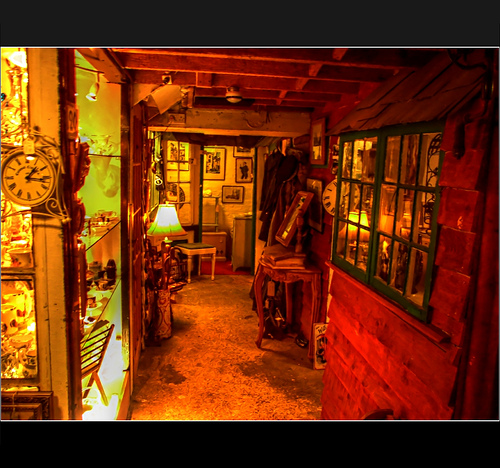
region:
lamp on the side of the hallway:
[146, 194, 189, 241]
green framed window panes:
[323, 123, 452, 332]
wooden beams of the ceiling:
[101, 48, 425, 125]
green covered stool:
[172, 230, 222, 287]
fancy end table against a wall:
[241, 245, 329, 366]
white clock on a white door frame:
[3, 148, 57, 218]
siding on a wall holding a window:
[314, 119, 484, 418]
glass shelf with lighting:
[51, 42, 129, 411]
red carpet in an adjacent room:
[193, 248, 256, 277]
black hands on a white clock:
[26, 165, 48, 192]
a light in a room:
[138, 148, 227, 263]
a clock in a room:
[9, 155, 59, 208]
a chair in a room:
[174, 204, 240, 282]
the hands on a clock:
[23, 163, 48, 187]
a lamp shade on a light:
[151, 193, 198, 239]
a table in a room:
[226, 232, 348, 357]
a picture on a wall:
[206, 157, 276, 195]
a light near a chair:
[161, 193, 244, 295]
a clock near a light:
[11, 133, 251, 231]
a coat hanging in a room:
[236, 160, 308, 257]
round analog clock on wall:
[0, 136, 62, 232]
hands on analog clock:
[16, 161, 56, 194]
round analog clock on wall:
[319, 172, 365, 232]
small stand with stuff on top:
[234, 178, 339, 366]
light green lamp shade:
[137, 189, 189, 256]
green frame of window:
[368, 111, 445, 326]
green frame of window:
[326, 123, 367, 297]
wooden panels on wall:
[313, 326, 393, 416]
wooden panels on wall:
[325, 293, 462, 431]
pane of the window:
[350, 139, 362, 177]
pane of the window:
[340, 146, 350, 177]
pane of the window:
[358, 231, 370, 270]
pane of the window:
[371, 239, 387, 282]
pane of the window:
[410, 253, 423, 301]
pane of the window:
[352, 228, 364, 269]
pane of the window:
[340, 223, 358, 260]